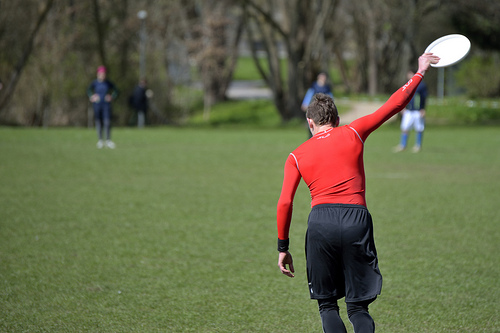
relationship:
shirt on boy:
[273, 73, 424, 245] [277, 32, 471, 330]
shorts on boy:
[303, 203, 380, 298] [277, 32, 471, 330]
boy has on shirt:
[277, 32, 471, 330] [273, 73, 424, 245]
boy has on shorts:
[277, 32, 471, 330] [303, 203, 380, 298]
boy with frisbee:
[277, 32, 471, 330] [412, 22, 479, 75]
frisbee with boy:
[412, 22, 479, 75] [277, 32, 471, 330]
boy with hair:
[277, 32, 471, 330] [303, 92, 340, 121]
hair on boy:
[303, 92, 340, 121] [277, 32, 471, 330]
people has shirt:
[88, 65, 121, 150] [85, 79, 119, 110]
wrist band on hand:
[277, 236, 289, 251] [276, 248, 292, 278]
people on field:
[88, 65, 121, 150] [1, 124, 484, 331]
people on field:
[130, 67, 151, 138] [1, 124, 484, 331]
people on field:
[394, 67, 427, 156] [1, 124, 484, 331]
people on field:
[309, 60, 329, 111] [1, 124, 484, 331]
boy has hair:
[277, 32, 471, 330] [293, 86, 368, 149]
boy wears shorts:
[277, 32, 471, 330] [298, 206, 398, 316]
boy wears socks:
[277, 32, 471, 330] [295, 303, 398, 331]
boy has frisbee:
[265, 29, 488, 331] [406, 10, 493, 80]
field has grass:
[57, 149, 257, 315] [1, 115, 497, 331]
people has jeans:
[88, 65, 121, 150] [89, 105, 125, 148]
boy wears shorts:
[277, 32, 471, 330] [303, 203, 385, 307]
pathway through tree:
[336, 90, 401, 126] [367, 9, 415, 86]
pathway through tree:
[336, 90, 401, 126] [264, 8, 331, 113]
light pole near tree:
[136, 10, 146, 130] [91, 0, 110, 65]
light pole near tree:
[136, 10, 146, 130] [111, 0, 128, 72]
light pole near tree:
[136, 10, 146, 130] [243, 0, 303, 121]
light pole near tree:
[136, 10, 146, 130] [178, 1, 246, 105]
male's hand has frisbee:
[416, 52, 440, 75] [424, 35, 472, 75]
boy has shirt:
[277, 32, 471, 330] [273, 73, 424, 245]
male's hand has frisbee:
[416, 52, 434, 75] [427, 37, 474, 71]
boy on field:
[277, 32, 471, 330] [1, 94, 497, 329]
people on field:
[393, 63, 428, 152] [1, 94, 497, 329]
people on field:
[88, 60, 122, 146] [1, 94, 497, 329]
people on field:
[302, 71, 332, 139] [1, 94, 497, 329]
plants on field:
[422, 92, 485, 131] [41, 156, 257, 314]